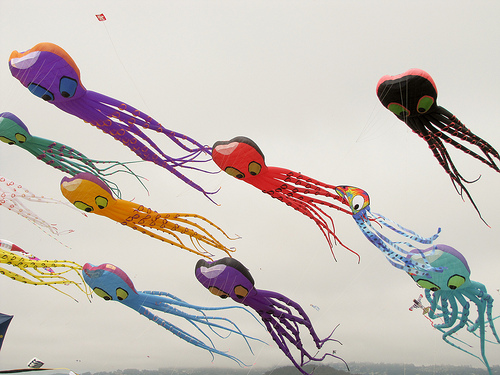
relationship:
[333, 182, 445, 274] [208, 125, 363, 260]
tie-dye kite behind orange kite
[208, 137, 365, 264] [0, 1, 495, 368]
squid in air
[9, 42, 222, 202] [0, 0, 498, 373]
kite in sky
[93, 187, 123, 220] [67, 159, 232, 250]
eyes on kite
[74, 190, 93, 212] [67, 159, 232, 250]
eyes on kite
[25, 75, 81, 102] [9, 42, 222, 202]
eyes on kite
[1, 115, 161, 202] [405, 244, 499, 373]
kite flying by kite